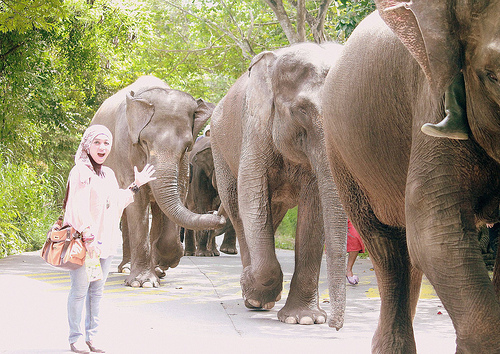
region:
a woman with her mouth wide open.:
[38, 126, 156, 353]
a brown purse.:
[39, 214, 89, 274]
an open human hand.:
[131, 157, 162, 192]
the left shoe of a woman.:
[83, 333, 110, 352]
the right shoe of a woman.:
[62, 333, 90, 352]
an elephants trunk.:
[142, 148, 227, 233]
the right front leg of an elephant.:
[235, 163, 283, 313]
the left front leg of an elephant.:
[270, 196, 328, 326]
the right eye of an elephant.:
[283, 96, 324, 138]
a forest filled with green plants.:
[0, 1, 377, 254]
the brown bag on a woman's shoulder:
[43, 218, 83, 274]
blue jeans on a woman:
[71, 268, 105, 342]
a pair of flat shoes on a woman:
[70, 341, 110, 353]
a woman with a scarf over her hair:
[76, 122, 111, 167]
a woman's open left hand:
[131, 157, 158, 199]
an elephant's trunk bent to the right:
[155, 166, 233, 243]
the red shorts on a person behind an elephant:
[348, 230, 366, 284]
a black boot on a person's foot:
[432, 87, 471, 148]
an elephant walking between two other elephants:
[208, 32, 368, 306]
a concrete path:
[151, 298, 272, 347]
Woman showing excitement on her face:
[38, 120, 160, 352]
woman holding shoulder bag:
[35, 118, 160, 353]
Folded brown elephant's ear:
[116, 83, 165, 149]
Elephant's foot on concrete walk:
[277, 263, 327, 330]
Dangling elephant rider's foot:
[384, 49, 498, 226]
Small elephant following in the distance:
[125, 73, 253, 292]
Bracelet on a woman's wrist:
[121, 161, 162, 196]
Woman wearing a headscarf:
[56, 118, 126, 203]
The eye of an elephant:
[269, 69, 327, 162]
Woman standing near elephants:
[35, 48, 356, 353]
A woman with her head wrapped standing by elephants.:
[56, 121, 158, 351]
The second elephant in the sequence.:
[203, 40, 353, 332]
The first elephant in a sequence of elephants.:
[317, 0, 499, 350]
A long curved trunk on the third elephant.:
[141, 142, 225, 232]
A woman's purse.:
[37, 179, 91, 269]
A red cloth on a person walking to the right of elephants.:
[342, 211, 369, 255]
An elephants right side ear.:
[125, 85, 152, 145]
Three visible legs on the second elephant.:
[207, 156, 332, 327]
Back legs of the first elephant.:
[335, 174, 422, 351]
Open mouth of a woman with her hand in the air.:
[93, 149, 105, 159]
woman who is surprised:
[42, 113, 157, 353]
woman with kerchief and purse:
[33, 116, 165, 351]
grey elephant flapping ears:
[77, 63, 231, 290]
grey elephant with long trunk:
[200, 39, 360, 345]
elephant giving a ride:
[316, 1, 498, 224]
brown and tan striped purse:
[34, 216, 105, 282]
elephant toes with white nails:
[277, 299, 331, 331]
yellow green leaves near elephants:
[11, 7, 71, 184]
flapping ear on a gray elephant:
[120, 83, 161, 151]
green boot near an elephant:
[409, 84, 494, 161]